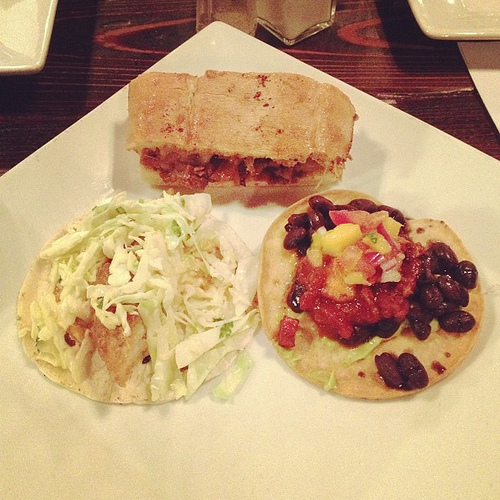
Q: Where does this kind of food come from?
A: Mexico.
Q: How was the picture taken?
A: From above.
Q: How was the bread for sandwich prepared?
A: Toasted.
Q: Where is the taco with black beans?
A: To the right.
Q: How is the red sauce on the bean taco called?
A: Salsa.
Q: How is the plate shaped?
A: Squared.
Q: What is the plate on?
A: A table.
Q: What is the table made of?
A: Wood.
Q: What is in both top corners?
A: Plates.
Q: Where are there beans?
A: Bottom right tortilla.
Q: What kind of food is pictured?
A: Tacos and a sandwich.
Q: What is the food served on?
A: A white plate.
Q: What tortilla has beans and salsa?
A: The one on the right.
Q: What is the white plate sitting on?
A: A table.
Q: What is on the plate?
A: Food.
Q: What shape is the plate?
A: Square.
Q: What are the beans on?
A: Tortilla.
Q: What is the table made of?
A: Wood.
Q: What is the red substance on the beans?
A: Tomatoes.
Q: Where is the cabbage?
A: Left of the tortilla with beans.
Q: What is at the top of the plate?
A: Sandwich.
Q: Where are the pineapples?
A: On the tomatoes.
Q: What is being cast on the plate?
A: Shadows.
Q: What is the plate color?
A: White.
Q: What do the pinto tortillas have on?
A: Beans.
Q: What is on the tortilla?
A: Lettuce.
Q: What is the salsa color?
A: Red and yellow.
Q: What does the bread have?
A: Inner filling.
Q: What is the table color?
A: Dark brown.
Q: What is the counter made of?
A: Wood.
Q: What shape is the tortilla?
A: Round.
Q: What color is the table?
A: Brown.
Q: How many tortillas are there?
A: Two.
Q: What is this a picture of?
A: Food.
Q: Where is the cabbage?
A: The left side.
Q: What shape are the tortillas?
A: Round.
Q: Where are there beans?
A: On the right.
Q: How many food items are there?
A: Three.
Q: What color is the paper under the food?
A: White.